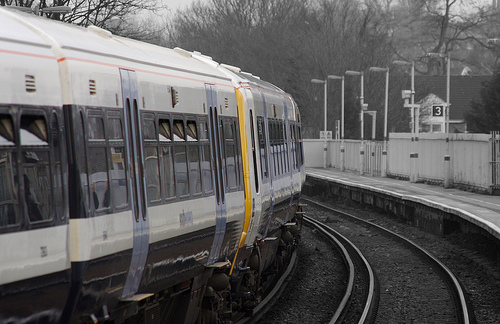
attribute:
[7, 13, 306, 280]
train — white, yellow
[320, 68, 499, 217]
train stop — empty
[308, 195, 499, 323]
railway — empty, metal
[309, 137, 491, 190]
fence — white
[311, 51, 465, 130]
lamps — white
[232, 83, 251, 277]
stripe — yellow